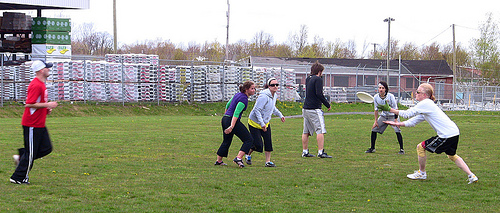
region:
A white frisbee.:
[352, 89, 376, 105]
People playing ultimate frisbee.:
[12, 42, 492, 207]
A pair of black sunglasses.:
[267, 81, 279, 88]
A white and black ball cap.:
[31, 58, 53, 70]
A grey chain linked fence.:
[10, 60, 498, 110]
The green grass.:
[4, 97, 497, 211]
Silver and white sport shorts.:
[299, 107, 326, 135]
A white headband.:
[265, 74, 276, 85]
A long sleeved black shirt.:
[302, 77, 329, 109]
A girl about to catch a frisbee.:
[352, 83, 482, 188]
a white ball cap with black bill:
[29, 59, 51, 69]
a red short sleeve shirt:
[22, 80, 47, 124]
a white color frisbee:
[357, 90, 372, 105]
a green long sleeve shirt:
[221, 90, 246, 123]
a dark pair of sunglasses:
[264, 83, 279, 87]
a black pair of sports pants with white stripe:
[17, 123, 54, 183]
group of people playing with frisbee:
[214, 60, 479, 186]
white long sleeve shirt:
[398, 99, 458, 136]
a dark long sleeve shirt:
[301, 75, 331, 109]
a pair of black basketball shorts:
[417, 132, 459, 152]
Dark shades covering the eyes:
[269, 82, 278, 87]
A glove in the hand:
[382, 105, 388, 109]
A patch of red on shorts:
[421, 140, 424, 147]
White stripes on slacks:
[30, 130, 33, 149]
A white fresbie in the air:
[356, 91, 373, 103]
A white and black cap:
[31, 61, 52, 67]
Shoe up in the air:
[12, 154, 19, 161]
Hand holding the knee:
[371, 121, 376, 128]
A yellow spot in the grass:
[366, 197, 368, 202]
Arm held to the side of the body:
[40, 103, 56, 108]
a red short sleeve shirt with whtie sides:
[23, 78, 46, 127]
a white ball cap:
[30, 59, 51, 70]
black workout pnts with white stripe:
[19, 126, 52, 186]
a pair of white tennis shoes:
[408, 169, 476, 183]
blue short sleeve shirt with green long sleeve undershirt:
[225, 94, 247, 119]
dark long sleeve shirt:
[303, 76, 328, 108]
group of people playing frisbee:
[212, 60, 478, 188]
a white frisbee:
[353, 90, 375, 105]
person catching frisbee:
[357, 83, 479, 183]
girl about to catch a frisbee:
[355, 81, 478, 186]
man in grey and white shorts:
[297, 60, 336, 162]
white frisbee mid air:
[353, 85, 377, 105]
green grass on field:
[2, 115, 497, 211]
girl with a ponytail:
[213, 77, 253, 170]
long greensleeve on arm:
[231, 101, 246, 119]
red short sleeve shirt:
[17, 75, 49, 126]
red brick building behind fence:
[252, 50, 454, 110]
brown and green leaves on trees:
[86, 33, 355, 61]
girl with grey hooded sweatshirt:
[245, 75, 287, 171]